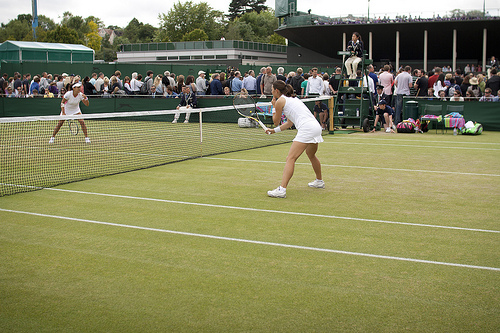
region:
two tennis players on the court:
[46, 80, 326, 197]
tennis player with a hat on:
[48, 81, 91, 144]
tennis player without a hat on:
[243, 81, 325, 198]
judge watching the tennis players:
[342, 32, 363, 79]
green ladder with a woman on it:
[328, 50, 377, 128]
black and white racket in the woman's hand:
[231, 92, 266, 132]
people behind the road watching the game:
[1, 72, 498, 99]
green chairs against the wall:
[420, 102, 465, 134]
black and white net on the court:
[0, 93, 333, 198]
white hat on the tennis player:
[69, 82, 81, 94]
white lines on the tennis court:
[167, 191, 465, 284]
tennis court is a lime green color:
[156, 189, 398, 330]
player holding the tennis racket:
[230, 78, 292, 142]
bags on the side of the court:
[396, 109, 498, 134]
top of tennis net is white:
[27, 105, 219, 119]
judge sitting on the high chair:
[338, 27, 367, 137]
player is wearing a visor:
[67, 74, 85, 92]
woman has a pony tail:
[273, 74, 303, 104]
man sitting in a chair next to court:
[174, 84, 201, 129]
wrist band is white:
[262, 118, 287, 140]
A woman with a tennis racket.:
[234, 62, 336, 222]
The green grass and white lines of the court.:
[153, 225, 266, 286]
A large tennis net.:
[2, 106, 210, 191]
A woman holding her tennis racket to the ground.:
[45, 78, 98, 142]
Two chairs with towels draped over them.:
[421, 100, 467, 137]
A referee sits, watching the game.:
[341, 28, 366, 81]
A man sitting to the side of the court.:
[171, 83, 196, 124]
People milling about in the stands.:
[89, 69, 174, 95]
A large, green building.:
[2, 38, 97, 63]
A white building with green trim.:
[114, 40, 287, 62]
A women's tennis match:
[0, 5, 497, 327]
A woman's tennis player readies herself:
[231, 77, 344, 200]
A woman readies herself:
[47, 75, 98, 145]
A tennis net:
[0, 102, 237, 197]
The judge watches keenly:
[338, 25, 368, 85]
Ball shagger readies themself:
[369, 100, 399, 137]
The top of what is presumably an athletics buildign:
[108, 27, 283, 62]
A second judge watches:
[169, 80, 197, 125]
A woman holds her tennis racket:
[214, 86, 274, 137]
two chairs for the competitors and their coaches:
[425, 102, 470, 138]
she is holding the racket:
[256, 118, 277, 135]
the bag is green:
[466, 123, 483, 135]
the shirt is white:
[288, 102, 301, 114]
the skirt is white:
[303, 126, 317, 137]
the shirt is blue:
[233, 77, 243, 89]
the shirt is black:
[417, 77, 426, 90]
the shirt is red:
[431, 74, 438, 83]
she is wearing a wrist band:
[270, 122, 283, 135]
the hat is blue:
[373, 96, 389, 108]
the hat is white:
[193, 67, 209, 78]